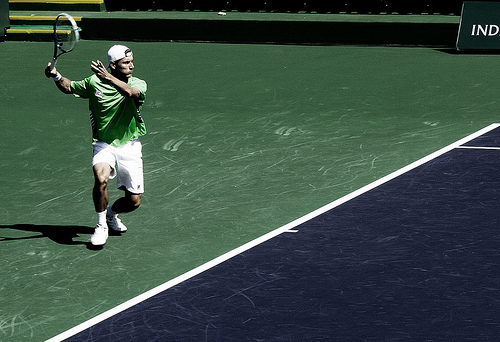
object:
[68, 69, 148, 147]
shirt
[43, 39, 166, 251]
player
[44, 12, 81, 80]
racket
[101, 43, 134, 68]
cap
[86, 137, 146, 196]
shorts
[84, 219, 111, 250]
shoes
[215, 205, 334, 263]
lines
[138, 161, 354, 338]
floor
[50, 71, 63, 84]
wristband